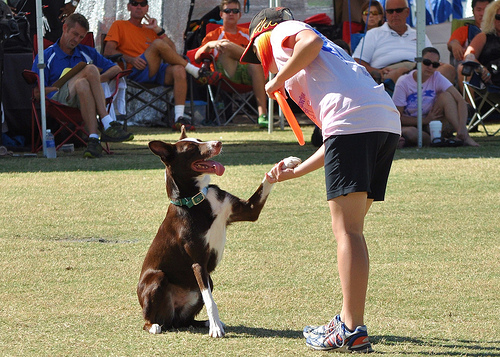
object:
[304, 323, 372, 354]
shoes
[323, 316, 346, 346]
laces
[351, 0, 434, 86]
man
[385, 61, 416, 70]
belt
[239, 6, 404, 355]
trainer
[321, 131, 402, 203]
black pants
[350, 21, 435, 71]
white top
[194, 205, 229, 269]
chest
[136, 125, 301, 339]
dog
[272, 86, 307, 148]
frisbee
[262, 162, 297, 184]
right hand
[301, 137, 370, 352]
left leg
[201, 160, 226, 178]
tongue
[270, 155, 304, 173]
dog's paw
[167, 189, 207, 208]
green collar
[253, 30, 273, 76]
orange hair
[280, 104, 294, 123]
orange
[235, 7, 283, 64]
cap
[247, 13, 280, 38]
red flames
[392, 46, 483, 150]
woman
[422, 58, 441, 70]
sunglasses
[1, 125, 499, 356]
ground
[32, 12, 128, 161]
man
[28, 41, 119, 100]
blue shirt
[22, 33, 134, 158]
chair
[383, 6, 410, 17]
dark glasses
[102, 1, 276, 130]
two men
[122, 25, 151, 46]
orange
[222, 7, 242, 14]
sunglasses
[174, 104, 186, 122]
sock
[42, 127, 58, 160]
bottled water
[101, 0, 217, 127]
man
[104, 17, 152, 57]
orange shirt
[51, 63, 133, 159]
crossed legs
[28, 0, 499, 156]
spectators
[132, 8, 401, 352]
trainer and dog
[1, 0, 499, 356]
show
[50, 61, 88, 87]
clipboard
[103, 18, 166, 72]
t-shirts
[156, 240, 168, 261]
brown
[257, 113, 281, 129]
shoes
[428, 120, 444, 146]
white cup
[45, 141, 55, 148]
blue lable